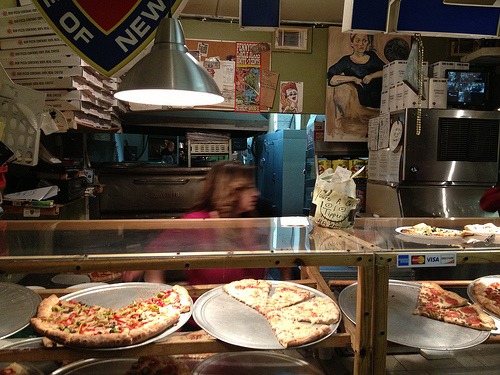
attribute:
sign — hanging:
[109, 19, 157, 68]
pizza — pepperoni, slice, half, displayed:
[100, 301, 157, 328]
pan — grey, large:
[218, 307, 245, 318]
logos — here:
[386, 244, 457, 270]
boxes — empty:
[42, 66, 84, 96]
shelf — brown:
[73, 131, 117, 141]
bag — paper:
[326, 172, 357, 188]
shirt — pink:
[172, 220, 195, 228]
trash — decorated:
[307, 160, 357, 190]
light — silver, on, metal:
[128, 21, 228, 105]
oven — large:
[416, 138, 480, 189]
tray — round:
[109, 291, 136, 307]